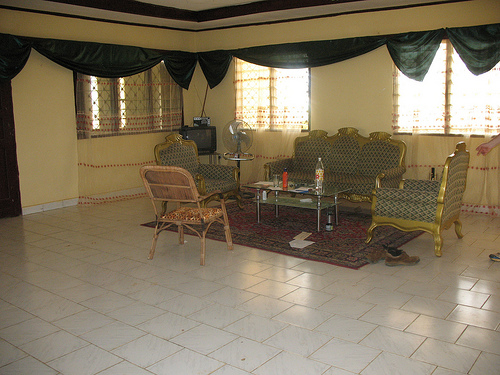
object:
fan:
[221, 118, 256, 199]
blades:
[242, 133, 251, 147]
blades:
[228, 122, 240, 134]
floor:
[0, 190, 500, 373]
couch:
[262, 127, 409, 208]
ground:
[413, 108, 451, 151]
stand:
[208, 152, 221, 164]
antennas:
[196, 95, 207, 117]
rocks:
[178, 125, 217, 154]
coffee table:
[242, 176, 352, 233]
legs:
[255, 201, 340, 232]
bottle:
[315, 157, 325, 186]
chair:
[140, 166, 234, 266]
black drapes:
[63, 39, 190, 91]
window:
[237, 54, 308, 130]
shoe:
[384, 250, 420, 268]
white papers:
[289, 231, 315, 248]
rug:
[140, 193, 428, 270]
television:
[179, 125, 217, 154]